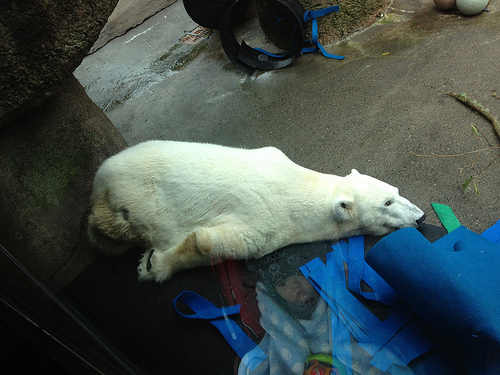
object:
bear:
[86, 139, 428, 286]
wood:
[0, 241, 136, 375]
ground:
[75, 0, 500, 375]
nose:
[415, 212, 426, 224]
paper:
[170, 290, 259, 359]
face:
[275, 270, 318, 306]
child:
[252, 243, 394, 374]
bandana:
[244, 241, 334, 319]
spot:
[174, 228, 212, 264]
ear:
[333, 197, 356, 220]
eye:
[384, 198, 394, 207]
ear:
[349, 169, 360, 176]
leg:
[161, 221, 259, 275]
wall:
[0, 0, 119, 126]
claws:
[134, 252, 150, 282]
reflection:
[255, 241, 333, 320]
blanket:
[236, 281, 413, 375]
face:
[356, 175, 426, 236]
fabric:
[363, 221, 500, 375]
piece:
[358, 304, 416, 357]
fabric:
[431, 200, 463, 235]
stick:
[445, 89, 500, 144]